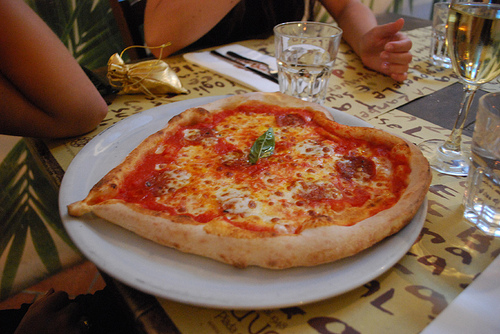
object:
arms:
[0, 0, 109, 138]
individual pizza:
[66, 91, 431, 270]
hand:
[360, 18, 412, 82]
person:
[124, 0, 411, 81]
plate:
[58, 95, 427, 310]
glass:
[463, 92, 500, 237]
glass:
[429, 2, 452, 70]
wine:
[446, 3, 500, 83]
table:
[20, 25, 500, 334]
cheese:
[226, 184, 264, 216]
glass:
[418, 0, 499, 177]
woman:
[0, 0, 107, 138]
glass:
[272, 21, 343, 104]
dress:
[119, 0, 314, 60]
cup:
[427, 2, 453, 69]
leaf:
[248, 127, 275, 164]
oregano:
[250, 127, 276, 165]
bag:
[107, 42, 189, 99]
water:
[464, 144, 499, 233]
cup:
[273, 21, 343, 103]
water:
[277, 44, 330, 102]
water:
[429, 23, 451, 61]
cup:
[463, 92, 500, 237]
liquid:
[278, 44, 331, 101]